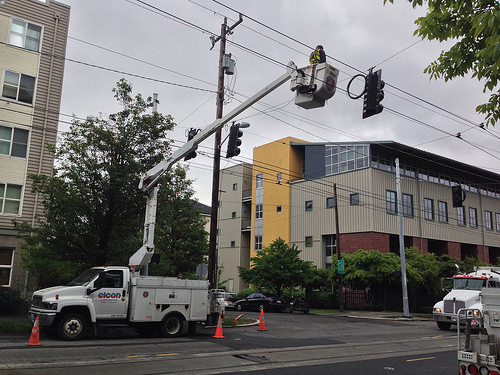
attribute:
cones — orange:
[210, 293, 297, 345]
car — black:
[212, 285, 326, 341]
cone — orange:
[207, 300, 235, 340]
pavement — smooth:
[254, 311, 397, 370]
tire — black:
[47, 300, 101, 347]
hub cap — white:
[66, 311, 80, 338]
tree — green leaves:
[44, 92, 211, 269]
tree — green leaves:
[55, 103, 215, 267]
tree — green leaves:
[63, 93, 202, 253]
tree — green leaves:
[86, 131, 147, 231]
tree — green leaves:
[255, 236, 307, 293]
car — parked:
[224, 285, 296, 315]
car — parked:
[226, 285, 300, 314]